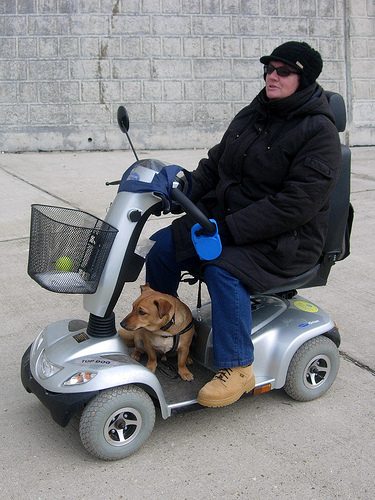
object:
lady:
[116, 39, 345, 410]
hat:
[260, 40, 324, 86]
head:
[265, 41, 324, 100]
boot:
[197, 364, 256, 409]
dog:
[120, 281, 197, 383]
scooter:
[18, 89, 354, 464]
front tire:
[78, 383, 157, 462]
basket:
[26, 203, 119, 294]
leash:
[191, 218, 223, 262]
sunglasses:
[263, 66, 303, 77]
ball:
[55, 256, 73, 272]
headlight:
[57, 369, 98, 387]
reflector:
[252, 382, 272, 395]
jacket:
[171, 81, 344, 295]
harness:
[153, 309, 196, 380]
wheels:
[78, 383, 156, 462]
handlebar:
[170, 188, 216, 234]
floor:
[114, 333, 219, 405]